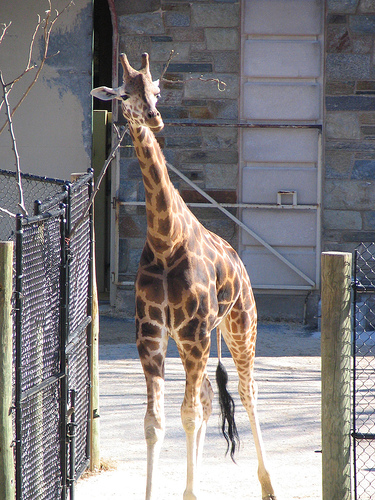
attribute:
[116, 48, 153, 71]
horns — on giraffe, brown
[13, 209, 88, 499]
door — chain link, on left, rusted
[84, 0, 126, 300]
pole — brown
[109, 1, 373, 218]
wall — brick, stone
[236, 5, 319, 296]
ladder — on wall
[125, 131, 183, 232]
giraffe neck — long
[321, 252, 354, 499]
pole — wooden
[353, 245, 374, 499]
fence — black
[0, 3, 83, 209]
limbs — wooden, bare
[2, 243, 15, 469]
fence — wooden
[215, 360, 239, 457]
tail end — black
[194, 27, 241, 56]
bricks — colored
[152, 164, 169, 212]
spots — dark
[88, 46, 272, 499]
giraffe — facing foward, in zoo, in pen, inside enclosure, tall, standing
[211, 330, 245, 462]
tail — black